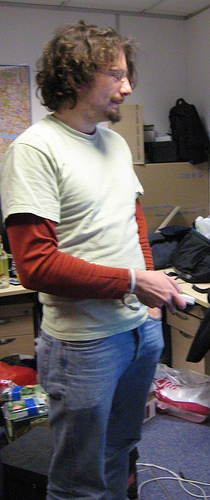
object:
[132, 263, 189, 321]
hand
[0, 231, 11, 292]
bottle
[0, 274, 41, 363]
desk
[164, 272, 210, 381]
desk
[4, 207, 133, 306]
red sleeve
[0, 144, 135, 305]
arm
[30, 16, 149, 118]
hair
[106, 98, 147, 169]
box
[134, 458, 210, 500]
cord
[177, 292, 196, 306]
remote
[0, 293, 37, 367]
cabinet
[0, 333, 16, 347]
handles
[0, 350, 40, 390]
bag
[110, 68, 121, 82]
glasses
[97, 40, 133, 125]
face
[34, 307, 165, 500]
blue jeans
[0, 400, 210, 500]
carpet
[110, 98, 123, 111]
lips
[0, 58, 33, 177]
map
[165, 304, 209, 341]
drawer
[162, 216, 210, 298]
bag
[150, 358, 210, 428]
plastic bag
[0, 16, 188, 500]
man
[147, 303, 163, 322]
hand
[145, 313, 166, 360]
pocket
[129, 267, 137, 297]
wristband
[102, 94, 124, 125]
goatee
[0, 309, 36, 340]
drawer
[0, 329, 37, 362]
drawer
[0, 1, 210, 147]
wall